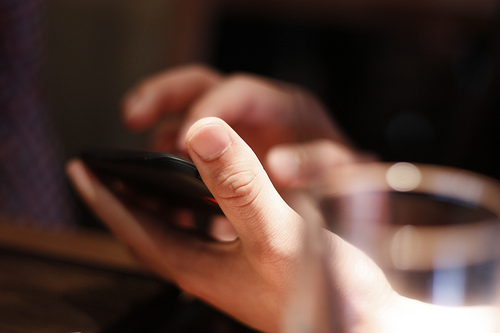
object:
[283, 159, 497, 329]
cup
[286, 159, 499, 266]
edge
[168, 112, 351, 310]
finger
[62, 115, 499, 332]
hand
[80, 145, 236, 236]
phone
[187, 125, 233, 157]
nail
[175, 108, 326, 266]
thumb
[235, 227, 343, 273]
knuckle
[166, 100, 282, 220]
thumb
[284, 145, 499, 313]
glass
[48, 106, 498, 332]
hand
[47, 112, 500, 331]
hand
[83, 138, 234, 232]
phone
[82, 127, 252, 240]
phone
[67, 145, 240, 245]
phone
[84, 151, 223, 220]
phone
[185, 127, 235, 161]
thumb nail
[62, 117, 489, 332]
hand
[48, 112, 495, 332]
hand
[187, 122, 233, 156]
fingernail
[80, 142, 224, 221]
phone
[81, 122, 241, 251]
phone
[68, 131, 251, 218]
cell phone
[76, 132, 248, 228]
cellphone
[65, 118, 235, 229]
phone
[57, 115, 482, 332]
hand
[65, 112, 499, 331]
hands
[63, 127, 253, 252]
cell phone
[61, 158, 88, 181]
tip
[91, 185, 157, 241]
finger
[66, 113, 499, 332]
left hand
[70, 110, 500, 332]
person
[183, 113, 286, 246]
thumb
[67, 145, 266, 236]
phone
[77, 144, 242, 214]
cell phone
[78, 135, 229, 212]
cellphone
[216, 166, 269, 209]
creases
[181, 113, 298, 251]
finger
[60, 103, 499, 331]
hand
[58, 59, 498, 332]
person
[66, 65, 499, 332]
woman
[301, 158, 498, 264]
cup edge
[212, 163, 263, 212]
wrinkles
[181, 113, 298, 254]
thumb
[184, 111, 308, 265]
person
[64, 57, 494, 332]
person